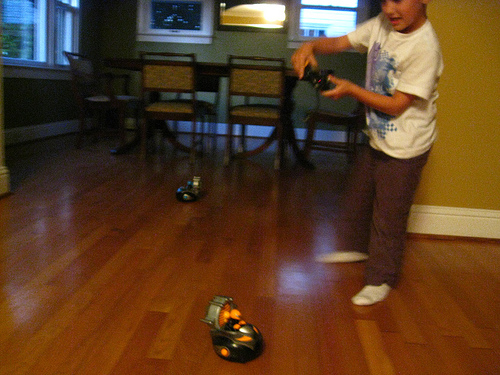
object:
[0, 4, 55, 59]
window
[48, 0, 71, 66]
window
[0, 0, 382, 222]
dining room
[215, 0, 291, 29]
mirror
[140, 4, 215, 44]
white window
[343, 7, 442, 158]
t-shirt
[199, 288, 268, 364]
car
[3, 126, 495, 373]
hardwood floor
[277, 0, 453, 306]
boy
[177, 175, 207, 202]
car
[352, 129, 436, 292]
pants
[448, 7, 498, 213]
wall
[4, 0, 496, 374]
living room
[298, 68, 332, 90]
remote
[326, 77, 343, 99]
hand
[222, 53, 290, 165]
chair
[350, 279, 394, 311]
socks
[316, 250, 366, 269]
socks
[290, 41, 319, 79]
hands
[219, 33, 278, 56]
wall